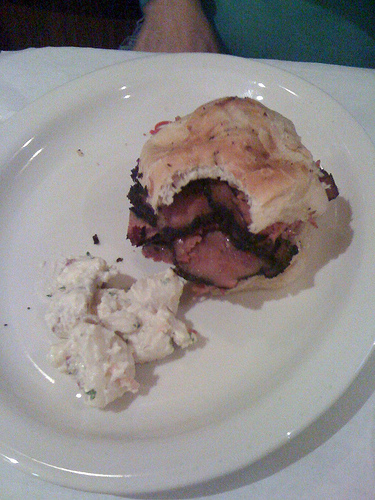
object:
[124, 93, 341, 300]
sandwich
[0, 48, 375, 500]
plate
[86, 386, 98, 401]
part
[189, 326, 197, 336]
part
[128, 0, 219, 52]
hand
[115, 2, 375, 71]
person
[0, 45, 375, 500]
table cloth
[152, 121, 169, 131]
thing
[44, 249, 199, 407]
food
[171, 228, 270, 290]
meat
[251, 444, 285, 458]
edge